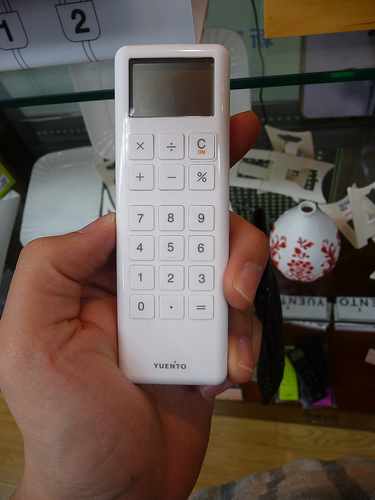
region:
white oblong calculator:
[102, 42, 228, 389]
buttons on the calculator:
[126, 131, 213, 330]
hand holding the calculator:
[15, 199, 265, 499]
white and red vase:
[271, 198, 343, 281]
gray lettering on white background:
[150, 359, 188, 371]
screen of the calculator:
[128, 58, 212, 116]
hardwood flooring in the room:
[3, 406, 374, 487]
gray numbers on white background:
[132, 209, 208, 316]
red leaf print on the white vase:
[267, 222, 318, 278]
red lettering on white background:
[196, 149, 205, 157]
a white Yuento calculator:
[83, 26, 251, 394]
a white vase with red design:
[270, 186, 346, 282]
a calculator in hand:
[15, 183, 270, 498]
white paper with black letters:
[272, 291, 374, 336]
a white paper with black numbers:
[3, 1, 130, 63]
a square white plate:
[19, 140, 136, 250]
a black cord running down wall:
[246, 2, 278, 107]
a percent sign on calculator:
[188, 166, 218, 191]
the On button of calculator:
[187, 128, 219, 166]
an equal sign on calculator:
[188, 294, 227, 327]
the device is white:
[114, 22, 229, 388]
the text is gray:
[150, 352, 188, 382]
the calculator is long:
[124, 46, 226, 352]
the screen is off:
[130, 56, 220, 116]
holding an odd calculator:
[73, 93, 250, 366]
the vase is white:
[278, 187, 353, 289]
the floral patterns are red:
[261, 225, 344, 278]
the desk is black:
[168, 179, 358, 395]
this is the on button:
[189, 124, 217, 164]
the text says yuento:
[145, 348, 190, 377]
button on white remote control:
[127, 134, 154, 159]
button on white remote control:
[130, 293, 154, 318]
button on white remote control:
[159, 293, 184, 318]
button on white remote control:
[189, 295, 213, 318]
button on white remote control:
[157, 165, 183, 190]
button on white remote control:
[186, 262, 211, 286]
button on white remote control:
[155, 262, 180, 285]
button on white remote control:
[127, 264, 152, 288]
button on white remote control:
[156, 233, 183, 258]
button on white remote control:
[158, 206, 183, 231]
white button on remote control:
[128, 133, 154, 158]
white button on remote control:
[129, 235, 152, 259]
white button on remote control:
[128, 264, 153, 289]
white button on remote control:
[128, 293, 154, 318]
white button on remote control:
[156, 292, 182, 317]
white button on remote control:
[188, 294, 210, 316]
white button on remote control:
[187, 265, 212, 288]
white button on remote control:
[158, 263, 182, 288]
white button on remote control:
[157, 235, 182, 259]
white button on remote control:
[188, 235, 213, 260]